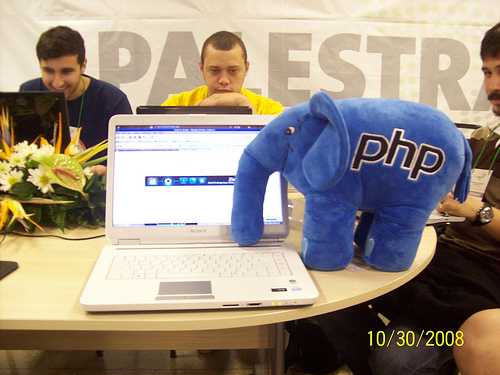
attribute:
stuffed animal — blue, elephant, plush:
[226, 89, 475, 275]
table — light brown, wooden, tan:
[1, 192, 442, 374]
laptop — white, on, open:
[81, 111, 321, 313]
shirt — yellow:
[152, 83, 293, 119]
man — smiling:
[10, 22, 139, 183]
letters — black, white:
[346, 126, 446, 185]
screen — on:
[111, 123, 285, 231]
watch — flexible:
[470, 200, 494, 229]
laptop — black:
[1, 84, 77, 155]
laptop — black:
[134, 100, 255, 116]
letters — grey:
[93, 26, 498, 125]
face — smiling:
[38, 53, 82, 98]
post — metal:
[273, 319, 290, 375]